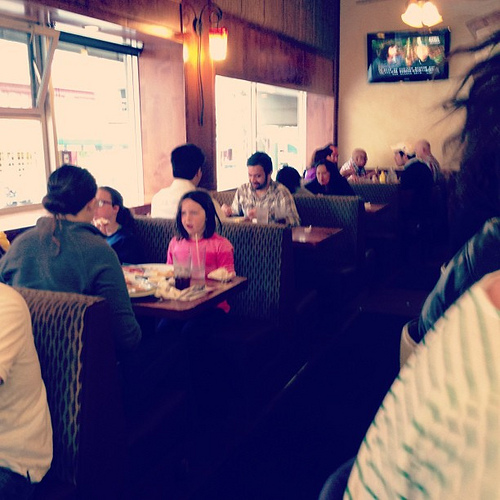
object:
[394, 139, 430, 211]
man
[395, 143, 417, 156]
cap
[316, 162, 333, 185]
head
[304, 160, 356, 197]
adult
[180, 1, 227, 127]
fixture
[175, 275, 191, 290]
coca cola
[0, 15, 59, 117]
window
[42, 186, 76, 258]
ponytail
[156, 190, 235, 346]
little girl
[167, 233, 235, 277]
pink shirt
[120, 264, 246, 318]
brown table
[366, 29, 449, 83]
framed picture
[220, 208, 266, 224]
adult diner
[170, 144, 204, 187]
head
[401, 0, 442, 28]
fixture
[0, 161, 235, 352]
family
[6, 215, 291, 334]
booth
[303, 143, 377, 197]
4 people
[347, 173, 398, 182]
table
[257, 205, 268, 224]
cup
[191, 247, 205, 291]
cup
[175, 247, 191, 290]
cup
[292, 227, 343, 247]
table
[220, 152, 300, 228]
guy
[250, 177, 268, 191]
beard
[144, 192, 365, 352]
booth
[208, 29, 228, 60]
light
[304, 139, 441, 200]
family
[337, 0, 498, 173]
wall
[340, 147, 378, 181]
man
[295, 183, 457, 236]
booth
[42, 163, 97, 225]
head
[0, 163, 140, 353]
adult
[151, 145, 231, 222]
adult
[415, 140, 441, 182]
people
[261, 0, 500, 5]
ceiling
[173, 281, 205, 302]
silverware